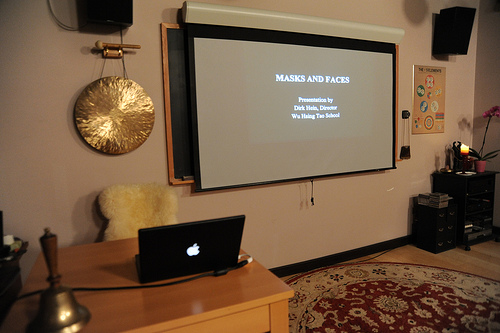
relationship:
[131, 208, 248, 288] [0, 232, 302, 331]
laptop on top of desk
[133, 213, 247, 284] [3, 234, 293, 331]
laptop on table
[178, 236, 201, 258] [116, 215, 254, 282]
apple on laptop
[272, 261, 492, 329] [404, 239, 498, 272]
rug on floor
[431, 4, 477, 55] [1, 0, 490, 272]
speaker on wall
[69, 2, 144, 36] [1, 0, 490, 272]
speaker on wall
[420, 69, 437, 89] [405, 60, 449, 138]
sticker on board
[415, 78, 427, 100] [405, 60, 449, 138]
sticker on board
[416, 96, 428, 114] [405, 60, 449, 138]
sticker on board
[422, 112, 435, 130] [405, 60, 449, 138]
sticker on board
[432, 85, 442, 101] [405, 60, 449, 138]
sticker on board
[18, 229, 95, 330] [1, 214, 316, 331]
bell on desk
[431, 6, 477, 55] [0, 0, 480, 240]
speaker on wall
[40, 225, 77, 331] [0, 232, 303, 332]
candle stick on desk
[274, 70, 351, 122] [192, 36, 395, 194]
words on projector screen